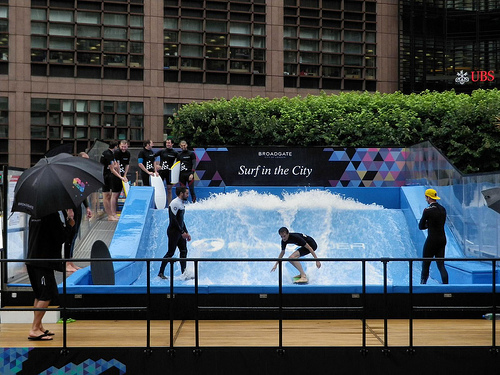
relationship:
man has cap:
[418, 185, 452, 288] [424, 188, 440, 199]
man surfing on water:
[418, 188, 449, 284] [129, 186, 440, 285]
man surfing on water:
[268, 225, 320, 285] [129, 186, 440, 285]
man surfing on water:
[156, 184, 192, 280] [129, 186, 440, 285]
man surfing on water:
[170, 139, 198, 202] [129, 186, 440, 285]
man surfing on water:
[156, 138, 174, 203] [129, 186, 440, 285]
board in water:
[79, 237, 120, 287] [129, 186, 440, 285]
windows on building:
[283, 3, 375, 88] [4, 0, 496, 154]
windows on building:
[406, 5, 498, 92] [4, 0, 496, 154]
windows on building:
[165, 2, 264, 84] [4, 0, 496, 154]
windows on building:
[33, 7, 146, 79] [4, 0, 496, 154]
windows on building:
[31, 93, 143, 156] [4, 0, 496, 154]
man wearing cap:
[418, 188, 449, 284] [423, 184, 442, 201]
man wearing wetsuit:
[418, 188, 449, 284] [417, 202, 449, 285]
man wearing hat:
[418, 188, 449, 284] [423, 184, 443, 202]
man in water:
[269, 226, 321, 284] [129, 186, 440, 285]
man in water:
[157, 186, 192, 280] [129, 186, 440, 285]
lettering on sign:
[237, 151, 313, 179] [225, 146, 327, 183]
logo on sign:
[453, 68, 469, 88] [453, 66, 499, 88]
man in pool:
[157, 186, 192, 280] [53, 177, 497, 300]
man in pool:
[269, 226, 321, 284] [53, 177, 497, 300]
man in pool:
[418, 188, 449, 284] [53, 177, 497, 300]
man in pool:
[269, 226, 321, 284] [61, 177, 499, 300]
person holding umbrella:
[23, 209, 79, 345] [10, 140, 108, 225]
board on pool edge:
[90, 239, 115, 285] [56, 278, 200, 318]